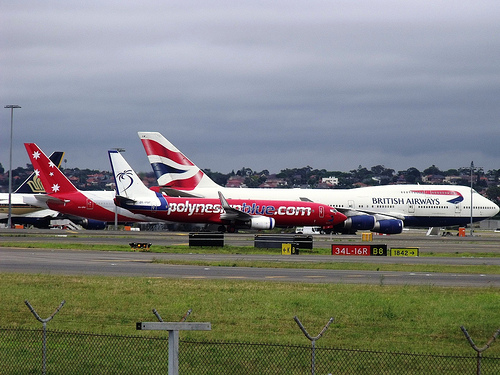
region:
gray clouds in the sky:
[15, 3, 395, 130]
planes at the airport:
[20, 106, 498, 254]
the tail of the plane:
[12, 133, 78, 199]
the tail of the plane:
[90, 138, 158, 203]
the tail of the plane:
[132, 126, 212, 191]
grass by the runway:
[16, 264, 491, 335]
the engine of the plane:
[215, 210, 280, 233]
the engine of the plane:
[328, 211, 376, 234]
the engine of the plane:
[377, 215, 406, 236]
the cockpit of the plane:
[438, 187, 485, 199]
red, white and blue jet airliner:
[105, 145, 350, 235]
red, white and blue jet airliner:
[132, 127, 497, 237]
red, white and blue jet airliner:
[15, 138, 158, 229]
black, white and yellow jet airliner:
[2, 148, 64, 223]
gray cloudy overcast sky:
[0, 0, 498, 178]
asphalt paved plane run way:
[2, 229, 499, 293]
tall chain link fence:
[0, 300, 497, 372]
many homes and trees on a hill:
[0, 165, 499, 200]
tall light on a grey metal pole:
[0, 92, 27, 235]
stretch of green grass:
[0, 268, 499, 374]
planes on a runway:
[14, 121, 494, 271]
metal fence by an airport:
[31, 303, 469, 371]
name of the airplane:
[367, 194, 448, 207]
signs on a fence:
[320, 235, 432, 265]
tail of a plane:
[132, 120, 206, 196]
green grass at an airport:
[66, 285, 285, 322]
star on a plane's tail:
[45, 178, 65, 197]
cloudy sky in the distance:
[186, 63, 459, 133]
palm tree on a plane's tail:
[115, 165, 141, 197]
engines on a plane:
[338, 208, 411, 245]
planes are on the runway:
[25, 135, 486, 252]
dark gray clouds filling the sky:
[84, 33, 426, 148]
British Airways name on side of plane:
[371, 192, 442, 212]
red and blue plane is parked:
[107, 192, 359, 219]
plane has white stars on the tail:
[28, 145, 68, 202]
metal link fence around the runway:
[27, 316, 197, 352]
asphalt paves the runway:
[185, 262, 275, 276]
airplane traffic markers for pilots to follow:
[329, 245, 421, 255]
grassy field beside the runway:
[154, 276, 378, 341]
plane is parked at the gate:
[15, 183, 88, 233]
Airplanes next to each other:
[1, 127, 498, 238]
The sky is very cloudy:
[1, 2, 498, 174]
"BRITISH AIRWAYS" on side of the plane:
[367, 194, 443, 207]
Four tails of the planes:
[16, 127, 220, 205]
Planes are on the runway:
[1, 131, 499, 252]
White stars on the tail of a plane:
[21, 138, 79, 194]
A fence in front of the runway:
[1, 295, 498, 373]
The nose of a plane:
[464, 182, 498, 228]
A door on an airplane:
[314, 203, 326, 221]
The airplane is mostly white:
[135, 124, 498, 237]